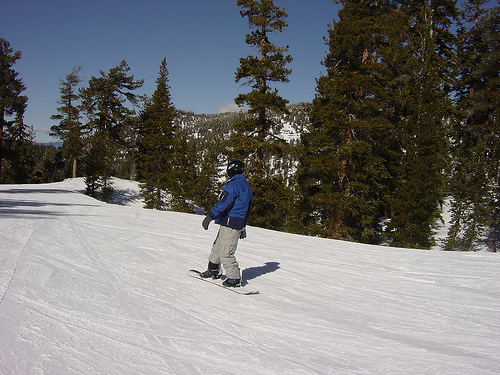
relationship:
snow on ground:
[24, 220, 175, 364] [33, 226, 220, 358]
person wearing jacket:
[202, 152, 257, 300] [208, 176, 252, 220]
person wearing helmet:
[202, 152, 257, 300] [225, 161, 247, 177]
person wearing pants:
[202, 152, 257, 300] [211, 220, 244, 281]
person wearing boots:
[202, 152, 257, 300] [204, 264, 246, 285]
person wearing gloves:
[202, 152, 257, 300] [203, 211, 212, 230]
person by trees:
[202, 152, 257, 300] [318, 20, 428, 241]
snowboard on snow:
[184, 262, 254, 303] [24, 220, 175, 364]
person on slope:
[202, 152, 257, 300] [47, 177, 170, 252]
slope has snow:
[47, 177, 170, 252] [24, 220, 175, 364]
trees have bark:
[318, 20, 428, 241] [347, 134, 352, 144]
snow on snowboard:
[24, 220, 175, 364] [184, 262, 254, 303]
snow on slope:
[24, 220, 175, 364] [47, 177, 170, 252]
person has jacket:
[202, 152, 257, 300] [208, 176, 252, 220]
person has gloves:
[202, 152, 257, 300] [203, 211, 212, 230]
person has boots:
[202, 152, 257, 300] [204, 264, 246, 285]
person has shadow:
[202, 152, 257, 300] [242, 259, 281, 285]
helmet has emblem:
[225, 161, 247, 177] [228, 161, 238, 171]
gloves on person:
[203, 211, 212, 230] [202, 152, 257, 300]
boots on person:
[204, 264, 246, 285] [202, 152, 257, 300]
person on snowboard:
[202, 152, 257, 300] [184, 262, 254, 303]